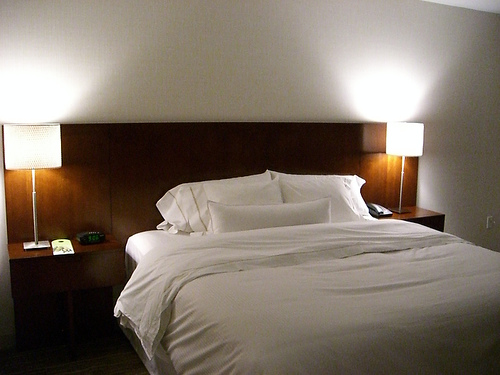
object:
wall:
[0, 122, 418, 336]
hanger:
[47, 234, 77, 257]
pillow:
[271, 171, 361, 222]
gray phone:
[367, 203, 393, 218]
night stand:
[367, 191, 448, 235]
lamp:
[385, 121, 425, 213]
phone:
[367, 194, 387, 221]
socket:
[486, 216, 493, 229]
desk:
[8, 234, 126, 339]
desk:
[369, 206, 446, 233]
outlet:
[484, 214, 495, 231]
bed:
[124, 219, 499, 375]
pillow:
[207, 196, 332, 233]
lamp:
[1, 110, 58, 267]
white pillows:
[203, 174, 283, 205]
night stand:
[6, 234, 106, 372]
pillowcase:
[156, 182, 212, 236]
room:
[0, 0, 497, 372]